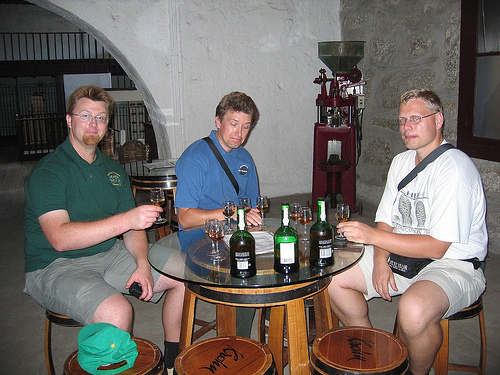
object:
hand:
[131, 204, 163, 231]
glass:
[216, 196, 237, 233]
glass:
[237, 197, 253, 230]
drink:
[228, 237, 257, 279]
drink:
[272, 244, 300, 273]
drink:
[307, 228, 336, 268]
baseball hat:
[76, 322, 138, 374]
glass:
[206, 220, 226, 262]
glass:
[334, 204, 350, 241]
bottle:
[229, 205, 256, 279]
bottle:
[273, 201, 298, 273]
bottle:
[309, 197, 335, 268]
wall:
[27, 0, 343, 204]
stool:
[390, 297, 488, 375]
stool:
[60, 336, 164, 375]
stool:
[40, 310, 132, 375]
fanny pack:
[386, 252, 435, 278]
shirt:
[21, 135, 138, 273]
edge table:
[147, 217, 365, 289]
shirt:
[374, 139, 490, 261]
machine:
[309, 39, 369, 221]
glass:
[149, 187, 168, 224]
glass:
[256, 195, 270, 228]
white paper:
[221, 230, 274, 255]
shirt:
[173, 129, 260, 230]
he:
[21, 83, 189, 369]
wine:
[150, 198, 166, 207]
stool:
[172, 335, 274, 375]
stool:
[307, 326, 410, 375]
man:
[175, 91, 262, 231]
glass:
[221, 199, 236, 235]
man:
[321, 89, 489, 375]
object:
[128, 281, 151, 303]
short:
[356, 244, 487, 321]